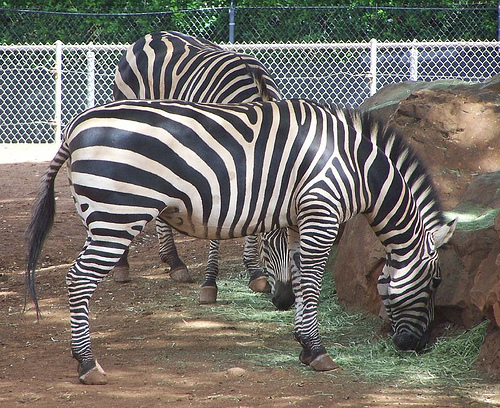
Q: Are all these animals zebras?
A: Yes, all the animals are zebras.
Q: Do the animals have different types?
A: No, all the animals are zebras.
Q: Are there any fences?
A: Yes, there is a fence.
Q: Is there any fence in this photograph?
A: Yes, there is a fence.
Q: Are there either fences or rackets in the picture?
A: Yes, there is a fence.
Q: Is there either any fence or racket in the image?
A: Yes, there is a fence.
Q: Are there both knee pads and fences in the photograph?
A: No, there is a fence but no knee pads.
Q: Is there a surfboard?
A: No, there are no surfboards.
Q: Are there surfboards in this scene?
A: No, there are no surfboards.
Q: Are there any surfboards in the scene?
A: No, there are no surfboards.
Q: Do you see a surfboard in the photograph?
A: No, there are no surfboards.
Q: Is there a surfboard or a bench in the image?
A: No, there are no surfboards or benches.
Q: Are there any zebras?
A: Yes, there are zebras.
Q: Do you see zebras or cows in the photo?
A: Yes, there are zebras.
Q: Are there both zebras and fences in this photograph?
A: Yes, there are both zebras and a fence.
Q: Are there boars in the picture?
A: No, there are no boars.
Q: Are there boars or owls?
A: No, there are no boars or owls.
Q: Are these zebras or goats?
A: These are zebras.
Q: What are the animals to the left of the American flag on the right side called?
A: The animals are zebras.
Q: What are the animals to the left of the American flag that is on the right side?
A: The animals are zebras.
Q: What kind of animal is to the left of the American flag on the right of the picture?
A: The animals are zebras.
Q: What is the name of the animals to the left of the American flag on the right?
A: The animals are zebras.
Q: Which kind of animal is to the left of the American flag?
A: The animals are zebras.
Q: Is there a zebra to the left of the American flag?
A: Yes, there are zebras to the left of the American flag.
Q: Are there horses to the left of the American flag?
A: No, there are zebras to the left of the American flag.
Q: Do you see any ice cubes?
A: No, there are no ice cubes.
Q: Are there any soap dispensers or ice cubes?
A: No, there are no ice cubes or soap dispensers.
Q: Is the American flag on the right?
A: Yes, the American flag is on the right of the image.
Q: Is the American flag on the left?
A: No, the American flag is on the right of the image.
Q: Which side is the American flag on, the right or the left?
A: The American flag is on the right of the image.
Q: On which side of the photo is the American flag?
A: The American flag is on the right of the image.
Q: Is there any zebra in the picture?
A: Yes, there is a zebra.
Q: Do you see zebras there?
A: Yes, there is a zebra.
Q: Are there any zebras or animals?
A: Yes, there is a zebra.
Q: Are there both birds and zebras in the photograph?
A: No, there is a zebra but no birds.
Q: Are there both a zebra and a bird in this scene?
A: No, there is a zebra but no birds.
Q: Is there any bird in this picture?
A: No, there are no birds.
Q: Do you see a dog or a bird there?
A: No, there are no birds or dogs.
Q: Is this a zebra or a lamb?
A: This is a zebra.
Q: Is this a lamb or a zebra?
A: This is a zebra.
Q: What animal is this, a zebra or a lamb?
A: This is a zebra.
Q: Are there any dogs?
A: No, there are no dogs.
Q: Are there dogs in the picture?
A: No, there are no dogs.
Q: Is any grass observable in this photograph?
A: Yes, there is grass.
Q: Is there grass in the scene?
A: Yes, there is grass.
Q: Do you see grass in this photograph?
A: Yes, there is grass.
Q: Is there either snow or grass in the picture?
A: Yes, there is grass.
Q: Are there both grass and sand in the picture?
A: No, there is grass but no sand.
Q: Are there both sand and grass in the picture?
A: No, there is grass but no sand.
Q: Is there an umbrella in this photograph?
A: No, there are no umbrellas.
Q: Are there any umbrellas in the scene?
A: No, there are no umbrellas.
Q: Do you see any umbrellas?
A: No, there are no umbrellas.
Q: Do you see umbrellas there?
A: No, there are no umbrellas.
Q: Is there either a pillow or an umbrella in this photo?
A: No, there are no umbrellas or pillows.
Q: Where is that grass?
A: The grass is on the ground.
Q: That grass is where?
A: The grass is on the ground.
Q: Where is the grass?
A: The grass is on the ground.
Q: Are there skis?
A: No, there are no skis.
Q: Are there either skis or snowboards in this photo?
A: No, there are no skis or snowboards.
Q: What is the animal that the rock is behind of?
A: The animal is a zebra.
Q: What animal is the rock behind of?
A: The rock is behind the zebra.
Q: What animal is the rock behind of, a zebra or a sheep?
A: The rock is behind a zebra.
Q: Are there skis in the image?
A: No, there are no skis.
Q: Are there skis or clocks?
A: No, there are no skis or clocks.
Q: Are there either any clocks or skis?
A: No, there are no skis or clocks.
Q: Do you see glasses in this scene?
A: No, there are no glasses.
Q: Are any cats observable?
A: No, there are no cats.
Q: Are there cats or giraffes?
A: No, there are no cats or giraffes.